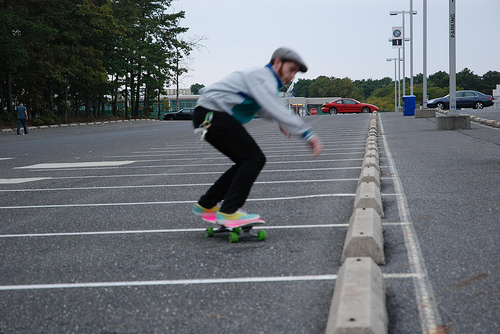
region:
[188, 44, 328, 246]
Man riding a skateboard in a parking lot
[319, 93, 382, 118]
Red car parked in the parking lot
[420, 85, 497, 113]
Small car parked in front of the blue container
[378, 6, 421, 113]
Three street lights in the parking lot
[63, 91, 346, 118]
Blue building behind the man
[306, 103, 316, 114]
Stop sign at the end of the parking lot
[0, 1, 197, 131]
Large green trees to the left of the man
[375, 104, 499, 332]
Walkway between the parking spaces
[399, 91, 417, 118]
Blue container in the walkway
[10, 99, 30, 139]
Man walking in the parking lot to the left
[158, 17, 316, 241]
the man is skateboarding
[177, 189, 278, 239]
the skateboard is pink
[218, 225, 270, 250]
the wheels are green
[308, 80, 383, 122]
a car is parked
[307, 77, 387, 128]
the car is red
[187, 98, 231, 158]
man has keys on the pants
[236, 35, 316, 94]
man is wearing a hat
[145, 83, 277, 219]
the pants are black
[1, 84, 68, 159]
person walking in the background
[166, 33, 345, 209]
man is leaning forward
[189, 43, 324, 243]
The man is on a skateboard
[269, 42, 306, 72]
The man is wearing a hat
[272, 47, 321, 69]
The hat is gray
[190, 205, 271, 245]
The skateboard is pink with green wheels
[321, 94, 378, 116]
The car is red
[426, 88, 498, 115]
The car is blue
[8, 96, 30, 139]
The man is wearing blue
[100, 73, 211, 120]
The building is turquoise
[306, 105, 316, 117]
The stop sign is red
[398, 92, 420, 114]
The trashcan is blue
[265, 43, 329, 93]
Man wearing hat on head.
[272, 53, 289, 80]
Man has dark side burns.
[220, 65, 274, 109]
Man wearing gray and blue jacket.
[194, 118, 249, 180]
Man wearing black pants.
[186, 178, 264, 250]
Man wearing colorful shoes.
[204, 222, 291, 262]
Green wheels on skateboard.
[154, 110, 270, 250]
Man standing on skateboard.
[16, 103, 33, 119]
Person wearing blue shirt.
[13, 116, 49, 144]
Person wearing blue pants.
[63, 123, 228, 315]
White lines marking pavement.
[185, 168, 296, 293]
Person on a rainbow skateboard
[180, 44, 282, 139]
person wearing a gray sweatshirt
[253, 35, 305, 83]
person wearing a gray hat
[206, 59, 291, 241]
person skate boarding in parking lot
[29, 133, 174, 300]
white paint on the asphalt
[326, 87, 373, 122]
red car in the parking lot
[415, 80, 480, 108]
blue car in the parking lot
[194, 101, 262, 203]
man wearing black pants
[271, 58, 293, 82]
man with big side burns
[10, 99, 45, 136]
person walking in the parking lot